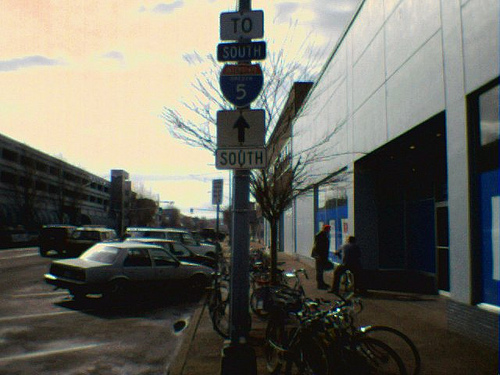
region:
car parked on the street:
[42, 235, 217, 306]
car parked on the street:
[126, 236, 221, 273]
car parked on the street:
[122, 225, 216, 260]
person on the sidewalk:
[306, 214, 342, 296]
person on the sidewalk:
[325, 229, 362, 302]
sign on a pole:
[212, 105, 274, 150]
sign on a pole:
[209, 145, 272, 169]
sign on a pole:
[215, 63, 266, 108]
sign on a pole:
[209, 36, 270, 66]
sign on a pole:
[212, 7, 265, 39]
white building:
[360, 52, 432, 103]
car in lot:
[55, 228, 192, 299]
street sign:
[198, 105, 283, 180]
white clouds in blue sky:
[8, 13, 50, 67]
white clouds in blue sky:
[22, 48, 62, 100]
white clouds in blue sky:
[65, 16, 117, 126]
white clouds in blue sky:
[112, 13, 187, 53]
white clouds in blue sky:
[111, 63, 163, 110]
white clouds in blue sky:
[102, 121, 157, 188]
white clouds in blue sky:
[281, 23, 323, 54]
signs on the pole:
[211, 10, 269, 371]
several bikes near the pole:
[256, 270, 425, 374]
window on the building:
[310, 182, 357, 211]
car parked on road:
[30, 238, 216, 305]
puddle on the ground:
[166, 313, 190, 340]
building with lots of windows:
[18, 160, 114, 205]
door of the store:
[432, 190, 453, 306]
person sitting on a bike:
[327, 226, 367, 309]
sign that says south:
[215, 150, 268, 171]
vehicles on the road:
[35, 223, 101, 250]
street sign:
[205, 52, 263, 100]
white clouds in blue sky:
[14, 69, 69, 119]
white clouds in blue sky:
[114, 21, 174, 71]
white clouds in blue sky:
[77, 101, 147, 152]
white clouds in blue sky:
[111, 143, 162, 185]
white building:
[361, 41, 452, 86]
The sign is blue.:
[212, 35, 277, 104]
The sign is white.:
[206, 109, 268, 173]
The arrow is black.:
[231, 113, 251, 145]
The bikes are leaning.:
[226, 242, 399, 374]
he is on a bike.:
[325, 237, 372, 294]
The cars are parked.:
[89, 221, 222, 306]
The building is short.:
[0, 138, 190, 243]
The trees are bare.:
[7, 148, 99, 245]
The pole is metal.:
[225, 178, 253, 371]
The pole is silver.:
[223, 170, 258, 368]